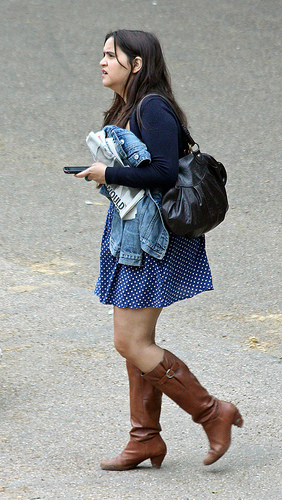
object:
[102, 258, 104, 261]
dot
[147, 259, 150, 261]
dot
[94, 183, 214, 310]
dress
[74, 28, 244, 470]
person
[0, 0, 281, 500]
sidewalk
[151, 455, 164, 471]
bottom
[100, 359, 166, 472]
shoe